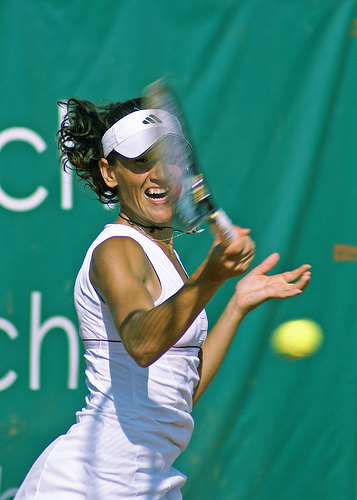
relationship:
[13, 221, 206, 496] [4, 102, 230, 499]
dress for tennis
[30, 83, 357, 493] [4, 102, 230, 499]
woman playing tennis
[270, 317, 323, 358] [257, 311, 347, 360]
ball in air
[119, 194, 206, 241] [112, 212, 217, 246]
woman has necklace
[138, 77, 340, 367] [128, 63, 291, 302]
player swinging racket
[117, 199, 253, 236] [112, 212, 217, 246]
pendant flying necklace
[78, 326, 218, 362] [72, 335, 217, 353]
band across dress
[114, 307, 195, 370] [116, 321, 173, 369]
shadow on elbow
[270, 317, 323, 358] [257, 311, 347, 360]
ball for air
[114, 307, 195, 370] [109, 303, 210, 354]
shadow of racket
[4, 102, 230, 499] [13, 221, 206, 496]
player in dress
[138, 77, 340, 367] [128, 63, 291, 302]
player has racket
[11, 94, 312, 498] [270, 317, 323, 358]
player hitting ball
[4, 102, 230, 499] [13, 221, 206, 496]
player wearing dress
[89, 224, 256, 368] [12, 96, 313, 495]
arm belonging to woman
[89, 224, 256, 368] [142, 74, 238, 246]
arm holding racket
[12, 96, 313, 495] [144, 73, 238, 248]
woman holding racquet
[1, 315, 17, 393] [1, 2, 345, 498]
letter printed on board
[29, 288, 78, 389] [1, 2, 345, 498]
letter printed on board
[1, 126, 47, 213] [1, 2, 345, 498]
letter printed on board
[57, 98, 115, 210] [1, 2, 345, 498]
letter printed on board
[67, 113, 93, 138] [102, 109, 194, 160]
curl flying behind visor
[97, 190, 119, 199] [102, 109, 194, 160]
curl flying behind visor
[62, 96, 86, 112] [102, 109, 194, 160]
curl flying behind visor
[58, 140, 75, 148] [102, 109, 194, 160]
curl flying behind visor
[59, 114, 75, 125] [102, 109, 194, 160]
curl flying behind visor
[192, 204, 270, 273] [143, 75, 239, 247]
hand holding tennis racket